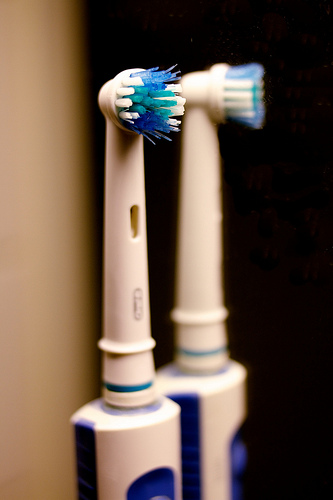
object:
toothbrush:
[65, 53, 189, 500]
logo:
[132, 285, 146, 324]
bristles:
[111, 59, 189, 151]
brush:
[90, 57, 191, 416]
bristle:
[225, 100, 254, 113]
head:
[94, 60, 192, 158]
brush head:
[164, 52, 269, 381]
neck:
[100, 124, 156, 396]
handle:
[170, 104, 230, 377]